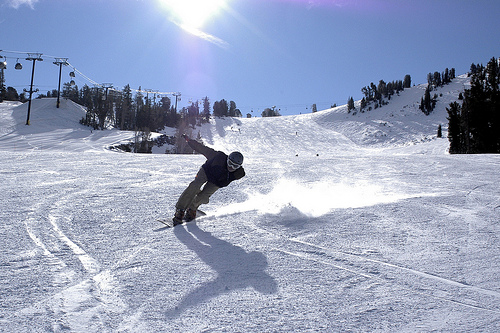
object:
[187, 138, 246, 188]
jacket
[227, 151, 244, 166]
helmet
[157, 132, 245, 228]
man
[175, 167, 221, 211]
pants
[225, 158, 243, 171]
goggles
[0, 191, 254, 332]
ground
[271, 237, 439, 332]
snow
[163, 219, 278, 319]
shadow